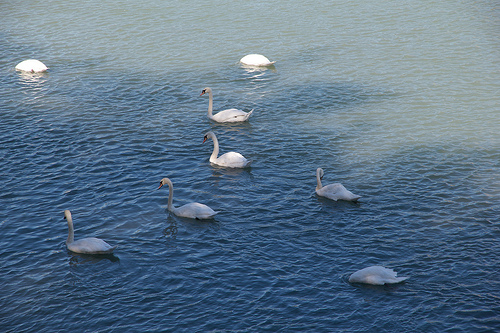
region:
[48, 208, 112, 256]
gray bird swimming in water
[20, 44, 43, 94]
gray bird swimming in water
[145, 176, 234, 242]
gray bird swimming in water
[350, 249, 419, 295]
gray bird swimming in water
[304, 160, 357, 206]
gray bird swimming in water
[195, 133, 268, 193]
gray bird swimming in water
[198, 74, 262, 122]
gray bird swimming in water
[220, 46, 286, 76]
gray bird swimming in water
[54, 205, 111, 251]
gray bird swimming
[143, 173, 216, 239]
gray bird swimming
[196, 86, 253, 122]
bird swimming in calm blue water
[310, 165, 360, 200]
bird swimming in calm blue water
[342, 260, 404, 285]
bird swimming in calm blue water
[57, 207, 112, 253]
bird swimming in calm blue water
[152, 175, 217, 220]
bird swimming in calm blue water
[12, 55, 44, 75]
bird swimming in calm blue water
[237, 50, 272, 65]
bird swimming in calm blue water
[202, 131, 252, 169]
bird swimming in calm blue water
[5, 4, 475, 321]
water body is partially in shade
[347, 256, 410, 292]
bird with head under water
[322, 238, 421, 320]
this is a bird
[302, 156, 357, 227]
this is a bird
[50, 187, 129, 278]
this is a bird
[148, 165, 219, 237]
this is a bird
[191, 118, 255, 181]
this is a bird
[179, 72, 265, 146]
this is a bird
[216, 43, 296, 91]
this is a bird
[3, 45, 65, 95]
this is a bird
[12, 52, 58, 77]
white duck swimming in water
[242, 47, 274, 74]
white duck swimming in water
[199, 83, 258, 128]
white duck swimming in water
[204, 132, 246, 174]
white duck swimming in water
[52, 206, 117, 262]
duck swimming in shade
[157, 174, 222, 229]
duck swimming in shade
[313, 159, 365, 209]
duck swimming in shade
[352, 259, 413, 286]
duck swimming in shade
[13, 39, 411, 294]
ducks in water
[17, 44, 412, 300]
ducks swimming in wavy water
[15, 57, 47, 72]
A white swan with it's head under water to the left.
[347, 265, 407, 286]
The bottom most white swan with it's head under water.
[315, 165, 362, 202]
A white swan above one with it's head underwater on the right.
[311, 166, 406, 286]
Two right most swans.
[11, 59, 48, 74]
Top left upper swan with head under water.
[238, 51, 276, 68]
Top most white swan with its head under water.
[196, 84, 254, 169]
Two swans in the middle with a shadow over them.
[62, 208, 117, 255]
Right side bottom swan in a shadow.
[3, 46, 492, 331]
The water that has a shadow cast on it.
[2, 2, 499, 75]
Top of the water with sun shining on it.